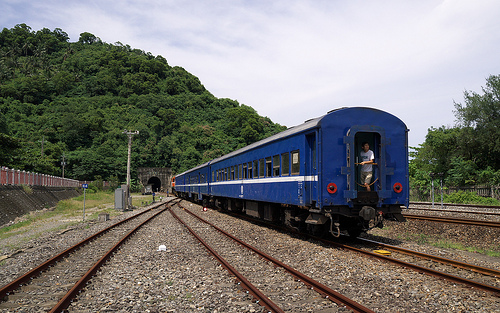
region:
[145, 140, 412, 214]
blue train on tracks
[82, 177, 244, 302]
multiple sets of railroad tracks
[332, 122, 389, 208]
man looking out the back of a train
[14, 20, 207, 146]
tree covered hill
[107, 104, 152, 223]
electrical wire pole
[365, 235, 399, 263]
something yellow on the tracks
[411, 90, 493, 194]
trees behind a train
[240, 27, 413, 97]
cloudy blue sky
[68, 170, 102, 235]
small blue sign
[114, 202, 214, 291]
rocky railroad track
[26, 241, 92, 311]
this is a railway line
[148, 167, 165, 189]
this is a tunnel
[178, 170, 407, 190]
this is a train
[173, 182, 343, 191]
the train is long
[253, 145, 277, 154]
the train is blue in color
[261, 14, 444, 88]
this is the sky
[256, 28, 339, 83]
the sky has clouds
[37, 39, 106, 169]
this is a hill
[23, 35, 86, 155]
the hill has a lot of trees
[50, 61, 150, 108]
the tree leaves are green in color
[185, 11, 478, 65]
this is the sky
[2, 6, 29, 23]
the sky is blue in color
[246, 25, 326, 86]
the sky has some clouds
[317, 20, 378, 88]
the clouds are white in color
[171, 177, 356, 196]
this is a train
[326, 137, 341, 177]
the train is blue in color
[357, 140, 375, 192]
a person standing at the train door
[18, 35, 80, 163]
this is a hill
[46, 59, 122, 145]
the hill is covered with many trees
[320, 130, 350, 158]
the train is blue in color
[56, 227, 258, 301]
these are two railway lines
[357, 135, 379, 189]
this is the train door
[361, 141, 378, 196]
a man is at the door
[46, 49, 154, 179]
this is a hill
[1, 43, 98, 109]
there are several trees on the hill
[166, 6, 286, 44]
the sky has some clouds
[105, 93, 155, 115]
the tree leaves are green in color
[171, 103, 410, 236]
blue train on train tracks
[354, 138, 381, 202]
man riding on a blue train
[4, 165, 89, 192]
fence for the rail yard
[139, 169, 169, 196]
train tunnel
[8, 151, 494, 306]
rail yard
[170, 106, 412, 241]
blue train about to enter tunnel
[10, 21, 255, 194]
forest covering train tunnel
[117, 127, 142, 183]
a train signal pole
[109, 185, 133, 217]
train track switch box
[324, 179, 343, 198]
red headlight on blue train